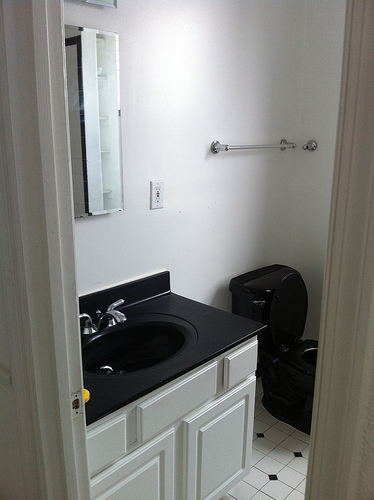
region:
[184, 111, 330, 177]
pole hanging on the wall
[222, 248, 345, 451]
toilet next to the sink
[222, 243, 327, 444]
the toilet is black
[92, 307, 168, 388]
the sink is black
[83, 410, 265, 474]
white drawers under the sink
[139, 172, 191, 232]
outlet in the wall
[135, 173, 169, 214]
the outlet is white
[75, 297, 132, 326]
silver faucet next to the sink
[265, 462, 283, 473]
tile on the floor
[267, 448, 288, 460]
tile on the floor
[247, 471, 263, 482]
tile on the floor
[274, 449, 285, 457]
tile on the floor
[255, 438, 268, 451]
tile on the floor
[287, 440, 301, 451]
tile on the floor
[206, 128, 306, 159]
this is a bar for a towel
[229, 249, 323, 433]
this is a toilet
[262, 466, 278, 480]
a small black tile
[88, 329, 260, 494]
the drawers and cabinet are white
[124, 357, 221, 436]
this is a wide drawer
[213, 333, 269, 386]
this drawer is smaller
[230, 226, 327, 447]
a black toilet in the corner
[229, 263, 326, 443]
a toilet color black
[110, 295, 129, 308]
handle of faucet on right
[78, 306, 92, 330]
handle of faucet on left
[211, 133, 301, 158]
a handle of silver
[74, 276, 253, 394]
counter of sink is black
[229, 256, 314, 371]
tank is color black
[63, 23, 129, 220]
a cabinet above the sink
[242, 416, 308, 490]
white and black tiles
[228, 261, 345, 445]
the toilet is black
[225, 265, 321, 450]
the toilet is black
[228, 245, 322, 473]
the toilet is black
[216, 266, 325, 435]
the toilet is black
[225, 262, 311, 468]
the toilet is black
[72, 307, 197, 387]
the sink is black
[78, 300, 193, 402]
the sink is black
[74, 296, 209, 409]
the sink is black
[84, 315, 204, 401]
the sink is black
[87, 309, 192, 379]
a black bathroom sink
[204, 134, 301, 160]
a silver towel rack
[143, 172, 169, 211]
white outlet on the wall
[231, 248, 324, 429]
black toilet on the side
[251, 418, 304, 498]
tile on the floor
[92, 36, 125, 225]
shelves in the medicine cabinet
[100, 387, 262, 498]
a set of cabinets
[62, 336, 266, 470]
a row of drawers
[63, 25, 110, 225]
mirror on the cabinet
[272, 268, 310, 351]
Lid of a toilet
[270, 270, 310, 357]
Lid of a toilet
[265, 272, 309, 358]
Lid of a toilet